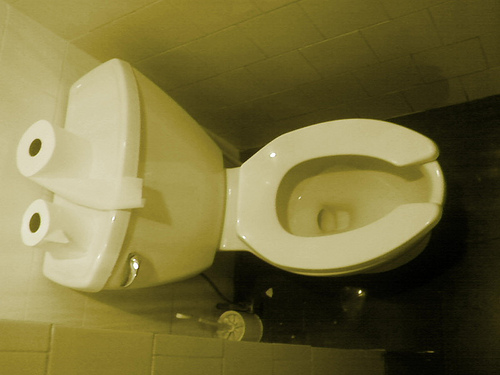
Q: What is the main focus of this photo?
A: A toilet.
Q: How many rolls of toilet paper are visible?
A: Two.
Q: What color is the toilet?
A: White.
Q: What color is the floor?
A: Black.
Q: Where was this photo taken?
A: Inside a bathroom.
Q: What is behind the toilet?
A: A toilet cleaning brush.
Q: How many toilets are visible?
A: One.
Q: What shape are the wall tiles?
A: Square.